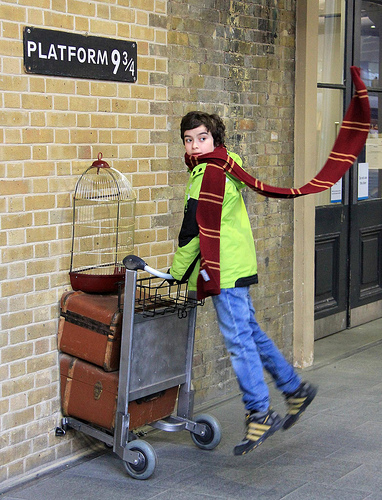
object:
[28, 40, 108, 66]
writing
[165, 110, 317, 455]
kid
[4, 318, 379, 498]
ground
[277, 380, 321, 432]
shoe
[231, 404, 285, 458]
shoe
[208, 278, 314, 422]
jeans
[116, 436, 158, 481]
object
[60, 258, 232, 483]
object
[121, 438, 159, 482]
wheel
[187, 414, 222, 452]
wheel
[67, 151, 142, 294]
cage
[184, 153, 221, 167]
neck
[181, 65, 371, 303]
scarf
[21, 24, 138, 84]
sign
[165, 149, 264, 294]
jacket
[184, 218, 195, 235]
black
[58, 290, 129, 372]
suitcase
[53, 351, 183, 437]
suitcase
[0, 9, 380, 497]
air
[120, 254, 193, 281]
handle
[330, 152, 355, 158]
stripe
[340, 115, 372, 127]
stripe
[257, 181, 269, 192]
stripe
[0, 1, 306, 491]
wall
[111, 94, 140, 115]
brick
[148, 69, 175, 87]
brick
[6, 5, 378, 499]
platform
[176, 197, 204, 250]
accent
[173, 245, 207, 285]
accent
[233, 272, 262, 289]
accent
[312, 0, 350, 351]
door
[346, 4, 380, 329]
door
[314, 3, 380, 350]
set